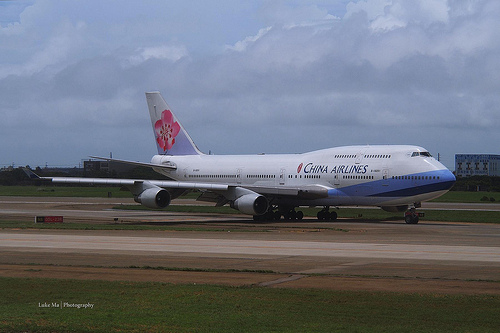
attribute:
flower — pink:
[149, 107, 180, 154]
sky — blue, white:
[249, 24, 372, 79]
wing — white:
[35, 175, 335, 217]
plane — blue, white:
[36, 89, 460, 224]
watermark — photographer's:
[31, 295, 98, 315]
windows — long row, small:
[123, 121, 445, 208]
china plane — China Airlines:
[29, 78, 460, 246]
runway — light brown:
[4, 221, 499, 279]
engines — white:
[130, 182, 270, 217]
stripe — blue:
[360, 166, 461, 190]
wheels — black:
[246, 192, 430, 237]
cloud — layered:
[1, 7, 493, 91]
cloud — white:
[3, 99, 495, 145]